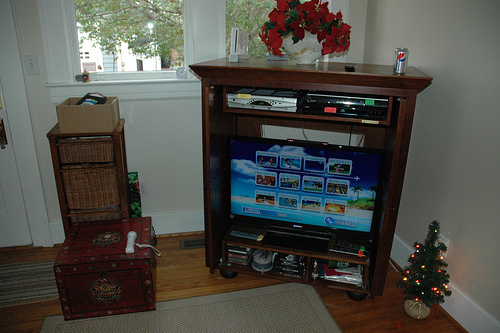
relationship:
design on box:
[89, 229, 125, 253] [53, 203, 159, 323]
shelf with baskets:
[41, 127, 135, 226] [56, 135, 114, 166]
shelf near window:
[41, 127, 135, 226] [41, 4, 207, 95]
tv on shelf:
[217, 133, 384, 250] [223, 225, 380, 275]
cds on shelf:
[227, 245, 307, 279] [223, 260, 309, 289]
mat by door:
[3, 253, 60, 316] [0, 13, 42, 256]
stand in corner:
[193, 42, 409, 298] [343, 2, 387, 71]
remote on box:
[120, 223, 147, 261] [53, 203, 159, 323]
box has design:
[53, 203, 159, 323] [85, 269, 123, 309]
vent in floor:
[174, 235, 206, 257] [156, 235, 201, 294]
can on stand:
[387, 42, 415, 83] [193, 42, 409, 298]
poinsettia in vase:
[266, 7, 345, 43] [282, 35, 323, 64]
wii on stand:
[227, 24, 248, 66] [193, 42, 409, 298]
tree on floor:
[397, 212, 457, 324] [384, 296, 458, 332]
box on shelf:
[223, 89, 300, 111] [226, 104, 391, 127]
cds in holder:
[251, 249, 271, 273] [254, 257, 266, 266]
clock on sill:
[169, 65, 195, 80] [78, 75, 178, 83]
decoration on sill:
[70, 66, 96, 85] [78, 75, 178, 83]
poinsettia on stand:
[266, 7, 345, 43] [193, 42, 409, 298]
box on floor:
[53, 203, 159, 323] [49, 299, 180, 325]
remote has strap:
[120, 223, 147, 261] [137, 241, 167, 257]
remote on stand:
[337, 54, 363, 79] [193, 42, 409, 298]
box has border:
[53, 203, 159, 323] [58, 256, 152, 275]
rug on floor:
[48, 286, 334, 331] [156, 235, 201, 294]